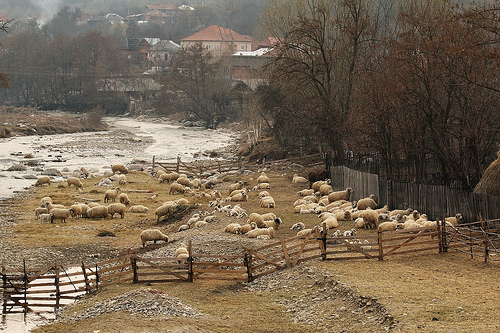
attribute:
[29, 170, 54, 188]
sheep — several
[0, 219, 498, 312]
fence — wooden, crooked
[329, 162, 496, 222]
fence — wooden, gray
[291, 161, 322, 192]
horse — brown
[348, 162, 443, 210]
fence — gray, wooden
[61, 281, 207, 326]
pile — large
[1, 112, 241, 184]
river — small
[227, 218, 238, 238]
sheep — laying down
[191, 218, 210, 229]
sheep — laying down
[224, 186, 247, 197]
sheep — laying down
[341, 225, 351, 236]
sheep — laying down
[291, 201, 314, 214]
sheep — laying down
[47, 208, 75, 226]
sheep — eating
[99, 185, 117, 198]
sheep — eating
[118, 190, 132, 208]
sheep — eating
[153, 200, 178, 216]
sheep — eating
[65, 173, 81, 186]
sheep — eating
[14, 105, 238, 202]
water — rushing